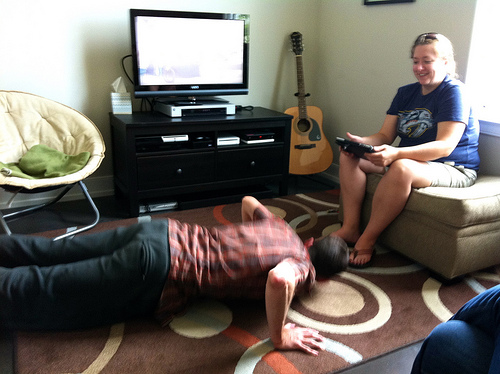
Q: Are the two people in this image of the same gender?
A: No, they are both male and female.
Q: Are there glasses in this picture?
A: No, there are no glasses.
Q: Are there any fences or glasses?
A: No, there are no glasses or fences.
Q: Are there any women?
A: Yes, there is a woman.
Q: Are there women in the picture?
A: Yes, there is a woman.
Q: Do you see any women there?
A: Yes, there is a woman.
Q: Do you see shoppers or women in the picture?
A: Yes, there is a woman.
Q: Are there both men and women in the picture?
A: Yes, there are both a woman and a man.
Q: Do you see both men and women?
A: Yes, there are both a woman and a man.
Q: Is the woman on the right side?
A: Yes, the woman is on the right of the image.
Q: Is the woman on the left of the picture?
A: No, the woman is on the right of the image.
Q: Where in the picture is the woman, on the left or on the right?
A: The woman is on the right of the image.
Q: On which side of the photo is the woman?
A: The woman is on the right of the image.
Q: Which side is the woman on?
A: The woman is on the right of the image.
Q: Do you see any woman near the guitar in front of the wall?
A: Yes, there is a woman near the guitar.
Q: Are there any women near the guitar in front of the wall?
A: Yes, there is a woman near the guitar.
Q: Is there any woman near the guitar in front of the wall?
A: Yes, there is a woman near the guitar.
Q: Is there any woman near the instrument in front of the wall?
A: Yes, there is a woman near the guitar.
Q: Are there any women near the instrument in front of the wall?
A: Yes, there is a woman near the guitar.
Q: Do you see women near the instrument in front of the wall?
A: Yes, there is a woman near the guitar.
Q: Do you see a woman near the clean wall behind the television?
A: Yes, there is a woman near the wall.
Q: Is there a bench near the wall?
A: No, there is a woman near the wall.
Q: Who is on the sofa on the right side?
A: The woman is on the sofa.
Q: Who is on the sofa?
A: The woman is on the sofa.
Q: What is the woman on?
A: The woman is on the sofa.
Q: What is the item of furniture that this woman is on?
A: The piece of furniture is a sofa.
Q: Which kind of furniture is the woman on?
A: The woman is on the sofa.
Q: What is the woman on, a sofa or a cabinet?
A: The woman is on a sofa.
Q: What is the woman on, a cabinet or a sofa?
A: The woman is on a sofa.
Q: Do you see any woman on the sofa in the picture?
A: Yes, there is a woman on the sofa.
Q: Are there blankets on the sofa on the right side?
A: No, there is a woman on the sofa.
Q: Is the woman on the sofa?
A: Yes, the woman is on the sofa.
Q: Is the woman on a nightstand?
A: No, the woman is on the sofa.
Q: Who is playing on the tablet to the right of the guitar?
A: The woman is playing on the tablet.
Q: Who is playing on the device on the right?
A: The woman is playing on the tablet.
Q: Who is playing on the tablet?
A: The woman is playing on the tablet.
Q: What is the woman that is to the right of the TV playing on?
A: The woman is playing on the tablet.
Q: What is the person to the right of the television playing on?
A: The woman is playing on the tablet.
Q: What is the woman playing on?
A: The woman is playing on the tablet.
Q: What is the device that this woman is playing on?
A: The device is a tablet.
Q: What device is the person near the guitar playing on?
A: The woman is playing on the tablet.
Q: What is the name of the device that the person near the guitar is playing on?
A: The device is a tablet.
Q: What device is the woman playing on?
A: The woman is playing on the tablet.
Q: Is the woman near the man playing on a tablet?
A: Yes, the woman is playing on a tablet.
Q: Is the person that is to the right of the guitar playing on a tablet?
A: Yes, the woman is playing on a tablet.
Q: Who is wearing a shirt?
A: The woman is wearing a shirt.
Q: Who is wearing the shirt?
A: The woman is wearing a shirt.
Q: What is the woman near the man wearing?
A: The woman is wearing a shirt.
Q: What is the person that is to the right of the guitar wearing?
A: The woman is wearing a shirt.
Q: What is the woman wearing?
A: The woman is wearing a shirt.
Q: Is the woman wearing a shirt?
A: Yes, the woman is wearing a shirt.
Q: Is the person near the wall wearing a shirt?
A: Yes, the woman is wearing a shirt.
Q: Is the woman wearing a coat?
A: No, the woman is wearing a shirt.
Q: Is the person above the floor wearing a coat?
A: No, the woman is wearing a shirt.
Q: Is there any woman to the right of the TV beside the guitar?
A: Yes, there is a woman to the right of the TV.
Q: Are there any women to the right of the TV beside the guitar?
A: Yes, there is a woman to the right of the TV.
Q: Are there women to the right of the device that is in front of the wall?
A: Yes, there is a woman to the right of the TV.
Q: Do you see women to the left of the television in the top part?
A: No, the woman is to the right of the TV.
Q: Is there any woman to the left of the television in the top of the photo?
A: No, the woman is to the right of the TV.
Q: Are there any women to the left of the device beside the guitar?
A: No, the woman is to the right of the TV.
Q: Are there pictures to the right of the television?
A: No, there is a woman to the right of the television.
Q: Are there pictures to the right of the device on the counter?
A: No, there is a woman to the right of the television.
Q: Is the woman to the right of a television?
A: Yes, the woman is to the right of a television.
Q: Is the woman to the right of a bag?
A: No, the woman is to the right of a television.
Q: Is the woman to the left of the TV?
A: No, the woman is to the right of the TV.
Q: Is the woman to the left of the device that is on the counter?
A: No, the woman is to the right of the TV.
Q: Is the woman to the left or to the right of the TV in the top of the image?
A: The woman is to the right of the TV.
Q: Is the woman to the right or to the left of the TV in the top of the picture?
A: The woman is to the right of the TV.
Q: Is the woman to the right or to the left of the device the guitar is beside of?
A: The woman is to the right of the TV.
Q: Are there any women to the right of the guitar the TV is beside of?
A: Yes, there is a woman to the right of the guitar.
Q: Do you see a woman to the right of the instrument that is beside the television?
A: Yes, there is a woman to the right of the guitar.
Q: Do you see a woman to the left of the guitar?
A: No, the woman is to the right of the guitar.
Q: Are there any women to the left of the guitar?
A: No, the woman is to the right of the guitar.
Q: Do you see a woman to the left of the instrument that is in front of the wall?
A: No, the woman is to the right of the guitar.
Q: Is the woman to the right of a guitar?
A: Yes, the woman is to the right of a guitar.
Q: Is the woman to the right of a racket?
A: No, the woman is to the right of a guitar.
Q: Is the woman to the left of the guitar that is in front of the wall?
A: No, the woman is to the right of the guitar.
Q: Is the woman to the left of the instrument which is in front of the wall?
A: No, the woman is to the right of the guitar.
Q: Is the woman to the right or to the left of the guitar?
A: The woman is to the right of the guitar.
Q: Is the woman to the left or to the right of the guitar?
A: The woman is to the right of the guitar.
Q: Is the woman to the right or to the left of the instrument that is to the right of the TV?
A: The woman is to the right of the guitar.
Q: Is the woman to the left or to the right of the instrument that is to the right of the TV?
A: The woman is to the right of the guitar.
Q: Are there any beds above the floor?
A: No, there is a woman above the floor.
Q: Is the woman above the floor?
A: Yes, the woman is above the floor.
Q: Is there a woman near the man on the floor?
A: Yes, there is a woman near the man.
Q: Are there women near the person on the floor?
A: Yes, there is a woman near the man.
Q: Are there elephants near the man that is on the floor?
A: No, there is a woman near the man.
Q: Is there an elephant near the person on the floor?
A: No, there is a woman near the man.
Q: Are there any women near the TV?
A: Yes, there is a woman near the TV.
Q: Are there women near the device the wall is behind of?
A: Yes, there is a woman near the TV.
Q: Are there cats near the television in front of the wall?
A: No, there is a woman near the TV.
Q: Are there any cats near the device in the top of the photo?
A: No, there is a woman near the TV.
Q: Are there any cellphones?
A: No, there are no cellphones.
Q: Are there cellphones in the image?
A: No, there are no cellphones.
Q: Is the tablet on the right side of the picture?
A: Yes, the tablet is on the right of the image.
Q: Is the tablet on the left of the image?
A: No, the tablet is on the right of the image.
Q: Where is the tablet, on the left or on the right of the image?
A: The tablet is on the right of the image.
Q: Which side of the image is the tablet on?
A: The tablet is on the right of the image.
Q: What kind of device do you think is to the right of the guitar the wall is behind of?
A: The device is a tablet.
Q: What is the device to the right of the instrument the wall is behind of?
A: The device is a tablet.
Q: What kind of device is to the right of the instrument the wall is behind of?
A: The device is a tablet.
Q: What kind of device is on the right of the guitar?
A: The device is a tablet.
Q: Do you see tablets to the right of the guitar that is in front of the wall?
A: Yes, there is a tablet to the right of the guitar.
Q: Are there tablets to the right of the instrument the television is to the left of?
A: Yes, there is a tablet to the right of the guitar.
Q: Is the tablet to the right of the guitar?
A: Yes, the tablet is to the right of the guitar.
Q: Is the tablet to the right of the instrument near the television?
A: Yes, the tablet is to the right of the guitar.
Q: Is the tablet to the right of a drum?
A: No, the tablet is to the right of the guitar.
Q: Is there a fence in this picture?
A: No, there are no fences.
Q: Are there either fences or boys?
A: No, there are no fences or boys.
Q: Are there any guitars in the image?
A: Yes, there is a guitar.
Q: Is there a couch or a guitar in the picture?
A: Yes, there is a guitar.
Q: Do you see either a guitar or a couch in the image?
A: Yes, there is a guitar.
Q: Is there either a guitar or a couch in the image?
A: Yes, there is a guitar.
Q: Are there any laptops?
A: No, there are no laptops.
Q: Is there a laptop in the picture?
A: No, there are no laptops.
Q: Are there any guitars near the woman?
A: Yes, there is a guitar near the woman.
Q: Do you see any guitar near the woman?
A: Yes, there is a guitar near the woman.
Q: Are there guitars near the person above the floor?
A: Yes, there is a guitar near the woman.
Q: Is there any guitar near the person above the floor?
A: Yes, there is a guitar near the woman.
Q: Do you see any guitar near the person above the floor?
A: Yes, there is a guitar near the woman.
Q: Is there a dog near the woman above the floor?
A: No, there is a guitar near the woman.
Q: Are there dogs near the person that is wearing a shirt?
A: No, there is a guitar near the woman.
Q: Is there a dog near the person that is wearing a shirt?
A: No, there is a guitar near the woman.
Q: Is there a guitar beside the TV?
A: Yes, there is a guitar beside the TV.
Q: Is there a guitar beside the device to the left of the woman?
A: Yes, there is a guitar beside the TV.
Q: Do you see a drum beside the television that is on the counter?
A: No, there is a guitar beside the TV.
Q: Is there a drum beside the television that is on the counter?
A: No, there is a guitar beside the TV.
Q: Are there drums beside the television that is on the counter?
A: No, there is a guitar beside the TV.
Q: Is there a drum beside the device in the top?
A: No, there is a guitar beside the TV.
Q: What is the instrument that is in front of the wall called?
A: The instrument is a guitar.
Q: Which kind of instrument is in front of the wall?
A: The instrument is a guitar.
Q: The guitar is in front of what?
A: The guitar is in front of the wall.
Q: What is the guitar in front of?
A: The guitar is in front of the wall.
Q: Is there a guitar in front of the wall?
A: Yes, there is a guitar in front of the wall.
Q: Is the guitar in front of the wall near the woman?
A: Yes, the guitar is in front of the wall.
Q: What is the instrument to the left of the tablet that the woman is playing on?
A: The instrument is a guitar.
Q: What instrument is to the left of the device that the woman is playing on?
A: The instrument is a guitar.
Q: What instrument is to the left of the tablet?
A: The instrument is a guitar.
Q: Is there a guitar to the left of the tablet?
A: Yes, there is a guitar to the left of the tablet.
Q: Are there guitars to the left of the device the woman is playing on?
A: Yes, there is a guitar to the left of the tablet.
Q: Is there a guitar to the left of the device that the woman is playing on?
A: Yes, there is a guitar to the left of the tablet.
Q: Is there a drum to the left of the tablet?
A: No, there is a guitar to the left of the tablet.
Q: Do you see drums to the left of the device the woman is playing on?
A: No, there is a guitar to the left of the tablet.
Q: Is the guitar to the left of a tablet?
A: Yes, the guitar is to the left of a tablet.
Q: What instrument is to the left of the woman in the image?
A: The instrument is a guitar.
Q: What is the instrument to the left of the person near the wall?
A: The instrument is a guitar.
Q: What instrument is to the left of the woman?
A: The instrument is a guitar.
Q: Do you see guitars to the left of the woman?
A: Yes, there is a guitar to the left of the woman.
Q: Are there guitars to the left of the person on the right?
A: Yes, there is a guitar to the left of the woman.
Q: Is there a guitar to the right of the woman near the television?
A: No, the guitar is to the left of the woman.